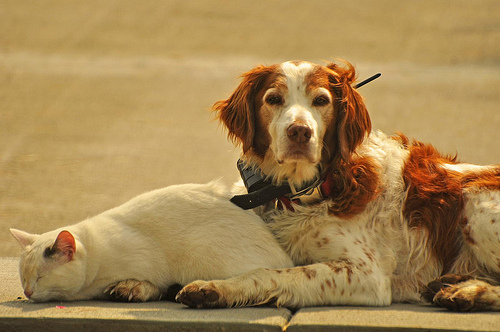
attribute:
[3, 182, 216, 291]
cat — sleeping, white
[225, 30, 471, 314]
dog — hairy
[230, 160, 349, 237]
collar — black, red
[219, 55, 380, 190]
ears — orange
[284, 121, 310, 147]
nose — brown